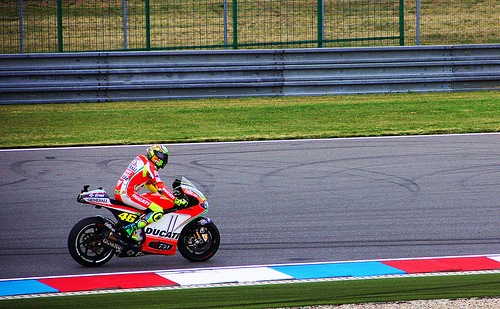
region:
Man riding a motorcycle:
[112, 145, 174, 241]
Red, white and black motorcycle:
[62, 175, 220, 261]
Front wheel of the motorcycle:
[176, 213, 221, 263]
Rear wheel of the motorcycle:
[65, 210, 121, 268]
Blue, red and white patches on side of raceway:
[0, 250, 495, 297]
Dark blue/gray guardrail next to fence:
[0, 38, 496, 105]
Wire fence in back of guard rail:
[0, 0, 496, 55]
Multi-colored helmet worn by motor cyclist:
[142, 138, 170, 168]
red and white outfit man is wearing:
[115, 150, 175, 210]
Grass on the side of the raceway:
[3, 92, 499, 149]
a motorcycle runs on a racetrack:
[60, 136, 230, 268]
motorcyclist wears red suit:
[108, 134, 178, 246]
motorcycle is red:
[68, 177, 227, 271]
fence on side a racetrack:
[3, 5, 498, 102]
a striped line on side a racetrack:
[1, 250, 496, 300]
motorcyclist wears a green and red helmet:
[130, 131, 170, 176]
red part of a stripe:
[390, 245, 495, 277]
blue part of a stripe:
[271, 252, 397, 284]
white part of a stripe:
[160, 260, 287, 292]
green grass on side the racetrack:
[10, 87, 496, 298]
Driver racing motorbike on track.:
[66, 143, 221, 268]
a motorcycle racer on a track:
[49, 143, 228, 265]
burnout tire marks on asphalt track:
[257, 145, 434, 228]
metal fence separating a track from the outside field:
[3, 1, 493, 103]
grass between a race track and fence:
[346, 98, 426, 127]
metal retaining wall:
[5, 55, 499, 90]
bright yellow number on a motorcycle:
[117, 208, 138, 225]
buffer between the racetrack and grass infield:
[2, 258, 492, 282]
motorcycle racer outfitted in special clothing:
[107, 140, 191, 254]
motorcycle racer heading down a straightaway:
[63, 143, 227, 268]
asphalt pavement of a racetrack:
[250, 142, 461, 239]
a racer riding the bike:
[58, 138, 243, 295]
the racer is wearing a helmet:
[141, 138, 175, 171]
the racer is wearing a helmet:
[141, 125, 187, 179]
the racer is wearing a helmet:
[129, 131, 213, 196]